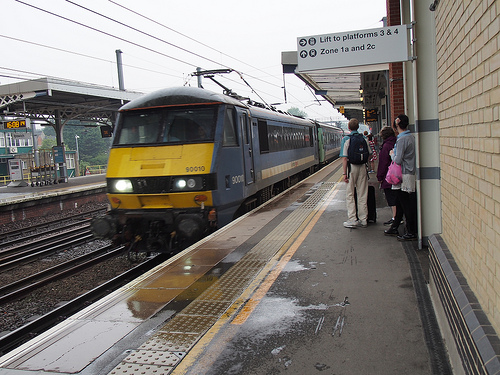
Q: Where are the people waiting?
A: On a train station platform.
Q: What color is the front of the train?
A: Yellow.